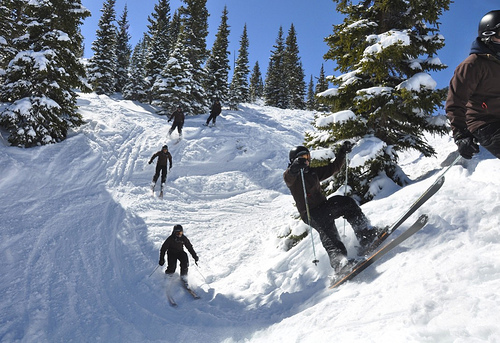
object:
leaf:
[333, 65, 341, 71]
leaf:
[424, 136, 430, 142]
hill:
[0, 90, 499, 343]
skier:
[445, 10, 500, 159]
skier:
[284, 145, 387, 274]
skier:
[158, 223, 201, 289]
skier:
[149, 145, 172, 188]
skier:
[166, 105, 185, 138]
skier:
[205, 98, 223, 127]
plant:
[0, 0, 91, 148]